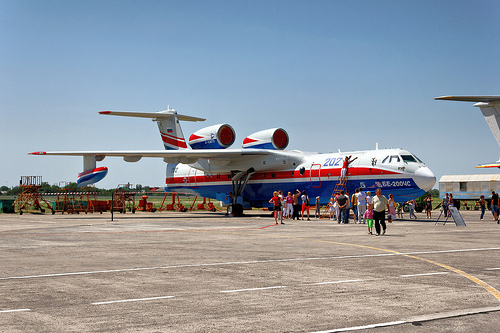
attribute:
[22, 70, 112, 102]
sky — clear, blue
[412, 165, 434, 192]
nose — white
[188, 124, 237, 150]
engine — white, blue, red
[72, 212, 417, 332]
lines — white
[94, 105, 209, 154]
tail — white, red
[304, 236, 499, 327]
yellowline — yellow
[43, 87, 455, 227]
plane — blue, white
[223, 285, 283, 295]
line — white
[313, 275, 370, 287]
line — white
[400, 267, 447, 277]
line — white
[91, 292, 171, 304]
line — white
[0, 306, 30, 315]
line — white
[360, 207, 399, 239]
pants — green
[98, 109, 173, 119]
wing — red, white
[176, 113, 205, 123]
wing — red, white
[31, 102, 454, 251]
plane — white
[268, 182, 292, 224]
person — red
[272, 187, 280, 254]
shorts — black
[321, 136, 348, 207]
numbers — blue